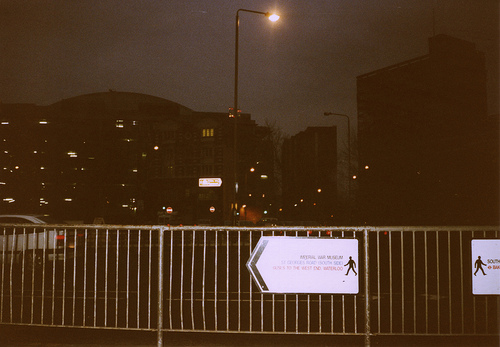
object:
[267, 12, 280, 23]
street light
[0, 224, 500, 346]
fence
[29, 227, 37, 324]
iron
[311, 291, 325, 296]
edge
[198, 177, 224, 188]
sign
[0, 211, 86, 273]
car parked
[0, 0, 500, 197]
sky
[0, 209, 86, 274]
car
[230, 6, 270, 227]
post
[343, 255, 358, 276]
image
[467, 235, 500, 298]
sign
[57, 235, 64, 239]
light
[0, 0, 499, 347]
city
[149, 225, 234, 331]
metal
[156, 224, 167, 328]
metal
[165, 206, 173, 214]
signs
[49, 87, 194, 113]
mountain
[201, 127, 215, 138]
window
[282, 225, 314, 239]
edge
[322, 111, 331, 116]
street light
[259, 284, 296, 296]
edge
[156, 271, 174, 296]
part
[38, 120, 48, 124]
light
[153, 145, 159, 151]
light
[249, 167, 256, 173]
light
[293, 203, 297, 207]
light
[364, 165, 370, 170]
light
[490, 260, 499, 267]
south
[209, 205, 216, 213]
street sign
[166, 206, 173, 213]
stop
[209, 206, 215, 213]
stop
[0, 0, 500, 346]
picture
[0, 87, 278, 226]
building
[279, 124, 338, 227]
building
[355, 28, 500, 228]
building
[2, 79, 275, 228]
place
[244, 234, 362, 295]
advertisement board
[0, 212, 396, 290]
parking area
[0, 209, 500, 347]
street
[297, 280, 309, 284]
part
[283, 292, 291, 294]
edge